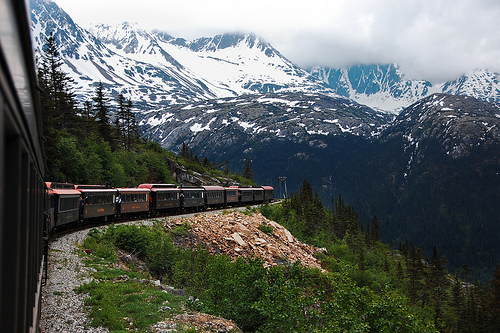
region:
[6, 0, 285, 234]
a train coming around a track through the mountain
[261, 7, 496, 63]
dense clouds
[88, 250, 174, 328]
patches of grass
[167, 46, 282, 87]
snow on a mountain top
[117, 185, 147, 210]
a car of a train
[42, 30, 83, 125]
a tall tree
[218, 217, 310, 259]
a rocky area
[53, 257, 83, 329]
a gravely area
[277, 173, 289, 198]
a road marker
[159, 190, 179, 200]
windows of a train car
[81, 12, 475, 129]
a few snow covered peaks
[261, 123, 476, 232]
a distant forest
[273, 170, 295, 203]
a tall wood structure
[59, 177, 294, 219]
a row of train cars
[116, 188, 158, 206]
a row of windows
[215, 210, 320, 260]
a brown rock pile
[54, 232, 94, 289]
some plants in the gravel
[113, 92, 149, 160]
a pair of tall trees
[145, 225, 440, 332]
a few short bushes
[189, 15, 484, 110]
a low hanging cloud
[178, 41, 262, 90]
snow on the mountains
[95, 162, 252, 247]
long train on tracks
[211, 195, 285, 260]
rocks next to train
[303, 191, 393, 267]
trees on the mountain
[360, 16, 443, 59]
cloud above the mountain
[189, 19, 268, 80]
mountain covered in clouds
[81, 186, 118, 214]
windows on the train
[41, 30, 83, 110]
tree on the mountain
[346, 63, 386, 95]
bare spot on mountain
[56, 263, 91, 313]
rocks next to train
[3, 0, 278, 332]
long black train on curved train track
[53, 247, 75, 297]
patch of grey gravel and rock on side of train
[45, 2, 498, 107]
snow covered mountains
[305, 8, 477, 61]
grey clouds in grey sky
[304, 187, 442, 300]
tall green trees on side of mountain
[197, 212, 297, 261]
patch of yellow debris on side of green steep mountain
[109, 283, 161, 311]
patch of short green grass at top of steep mountain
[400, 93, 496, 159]
brown rock mountain formaton with sporadic snow patches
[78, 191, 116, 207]
row of windows on side of train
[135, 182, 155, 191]
red corner of train roof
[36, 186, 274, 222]
A train on tracks.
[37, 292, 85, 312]
Gravel around the tracks.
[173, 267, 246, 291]
The grass is green.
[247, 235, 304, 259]
Woodchips on the ground.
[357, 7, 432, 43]
Clouds in the sky.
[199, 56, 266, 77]
Snow on the mountains.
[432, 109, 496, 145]
The mountains are black.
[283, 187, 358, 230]
The trees are green.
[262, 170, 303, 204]
Tunnel in the mountain.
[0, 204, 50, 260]
Train car next to the camera.